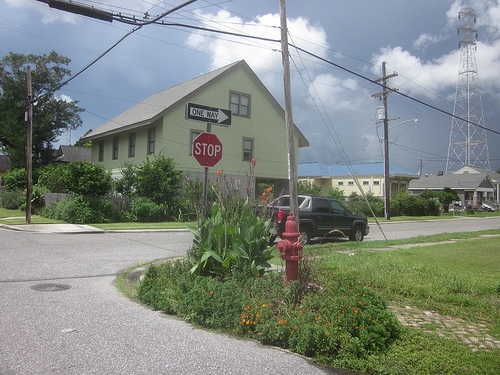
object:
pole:
[278, 0, 299, 231]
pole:
[381, 62, 389, 220]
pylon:
[446, 5, 490, 171]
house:
[80, 59, 312, 210]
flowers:
[244, 321, 252, 324]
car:
[262, 193, 370, 247]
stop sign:
[191, 131, 222, 168]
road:
[0, 215, 500, 375]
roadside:
[107, 270, 374, 375]